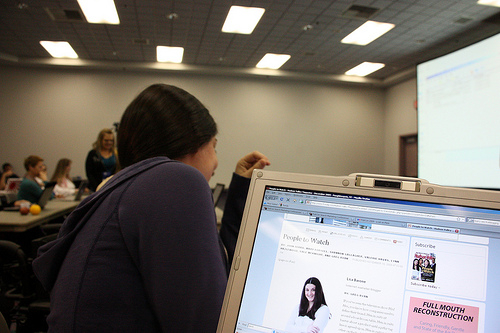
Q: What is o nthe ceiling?
A: Lights.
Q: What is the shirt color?
A: Blue.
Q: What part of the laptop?
A: Screen.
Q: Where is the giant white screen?
A: On the wall.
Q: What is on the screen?
A: A webpage.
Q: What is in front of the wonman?
A: Computer screen.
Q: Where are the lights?
A: On the ceiling.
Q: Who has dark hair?
A: The woman.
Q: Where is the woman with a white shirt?
A: On the screen.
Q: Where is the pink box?
A: On the screen.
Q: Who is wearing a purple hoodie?
A: The woman.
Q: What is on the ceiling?
A: The lights.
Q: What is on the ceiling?
A: Lights.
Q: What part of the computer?
A: Screen.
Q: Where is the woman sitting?
A: Behind hte computer.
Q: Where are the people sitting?
A: Background.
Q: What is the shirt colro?
A: Blue.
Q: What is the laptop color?
A: Silver.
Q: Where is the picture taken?
A: Classroom.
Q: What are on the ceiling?
A: Lights.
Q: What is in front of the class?
A: Projector screen.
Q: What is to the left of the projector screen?
A: Door.